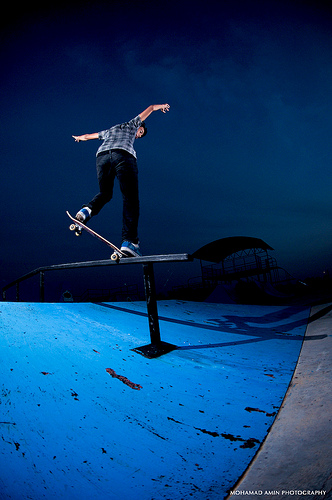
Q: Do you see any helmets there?
A: No, there are no helmets.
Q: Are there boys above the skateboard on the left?
A: Yes, there is a boy above the skateboard.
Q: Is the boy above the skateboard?
A: Yes, the boy is above the skateboard.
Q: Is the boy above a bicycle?
A: No, the boy is above the skateboard.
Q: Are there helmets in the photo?
A: No, there are no helmets.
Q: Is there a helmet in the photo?
A: No, there are no helmets.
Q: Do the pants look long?
A: Yes, the pants are long.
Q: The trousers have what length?
A: The trousers are long.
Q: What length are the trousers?
A: The trousers are long.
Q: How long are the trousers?
A: The trousers are long.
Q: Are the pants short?
A: No, the pants are long.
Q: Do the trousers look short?
A: No, the trousers are long.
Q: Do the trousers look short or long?
A: The trousers are long.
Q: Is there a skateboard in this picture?
A: Yes, there is a skateboard.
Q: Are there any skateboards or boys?
A: Yes, there is a skateboard.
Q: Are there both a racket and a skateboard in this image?
A: No, there is a skateboard but no rackets.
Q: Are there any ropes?
A: No, there are no ropes.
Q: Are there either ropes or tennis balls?
A: No, there are no ropes or tennis balls.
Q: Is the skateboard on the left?
A: Yes, the skateboard is on the left of the image.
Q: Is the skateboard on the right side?
A: No, the skateboard is on the left of the image.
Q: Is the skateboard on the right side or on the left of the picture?
A: The skateboard is on the left of the image.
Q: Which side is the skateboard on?
A: The skateboard is on the left of the image.